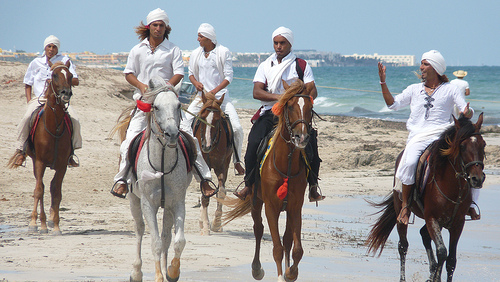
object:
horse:
[364, 112, 485, 282]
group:
[10, 8, 474, 226]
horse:
[28, 58, 72, 235]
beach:
[0, 62, 498, 280]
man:
[233, 26, 325, 202]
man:
[14, 35, 82, 167]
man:
[177, 23, 249, 176]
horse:
[210, 79, 318, 282]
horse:
[188, 90, 234, 236]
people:
[22, 6, 481, 225]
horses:
[9, 58, 487, 282]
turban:
[271, 26, 293, 47]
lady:
[378, 50, 475, 225]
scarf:
[263, 51, 296, 95]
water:
[110, 66, 499, 125]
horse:
[118, 77, 197, 281]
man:
[109, 7, 219, 197]